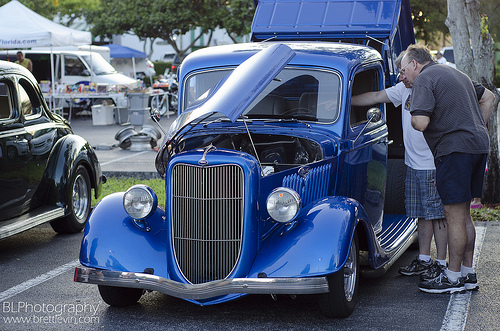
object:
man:
[401, 42, 491, 295]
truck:
[70, 1, 423, 318]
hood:
[154, 43, 338, 178]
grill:
[169, 161, 245, 284]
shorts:
[403, 165, 446, 222]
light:
[121, 184, 154, 219]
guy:
[352, 51, 449, 281]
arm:
[350, 83, 401, 108]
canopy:
[0, 0, 93, 47]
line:
[440, 224, 485, 329]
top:
[383, 81, 437, 173]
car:
[0, 58, 107, 244]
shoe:
[419, 274, 467, 295]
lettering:
[84, 301, 92, 312]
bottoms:
[432, 151, 489, 207]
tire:
[48, 163, 93, 235]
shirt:
[408, 60, 489, 155]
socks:
[444, 268, 463, 282]